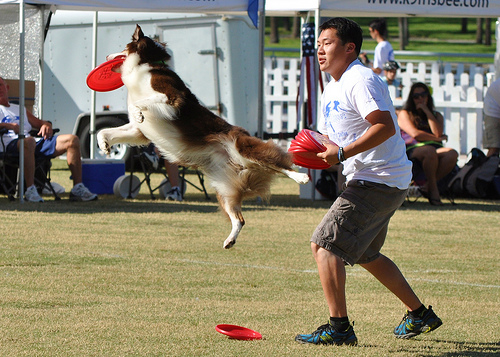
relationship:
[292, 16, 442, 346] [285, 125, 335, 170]
man has frisbees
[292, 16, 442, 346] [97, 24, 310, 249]
man playing with dog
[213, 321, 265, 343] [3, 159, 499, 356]
frisbee on ground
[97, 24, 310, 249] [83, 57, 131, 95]
dog has frisbee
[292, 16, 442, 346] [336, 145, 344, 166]
man has bracelet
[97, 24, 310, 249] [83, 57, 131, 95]
dog catching frisbee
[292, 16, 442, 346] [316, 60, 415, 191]
man has tshirt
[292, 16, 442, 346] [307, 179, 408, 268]
man wearing shorts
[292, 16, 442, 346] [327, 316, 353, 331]
man wearing socks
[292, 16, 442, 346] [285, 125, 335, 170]
man holding frisbees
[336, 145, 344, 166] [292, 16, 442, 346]
bracelet on man